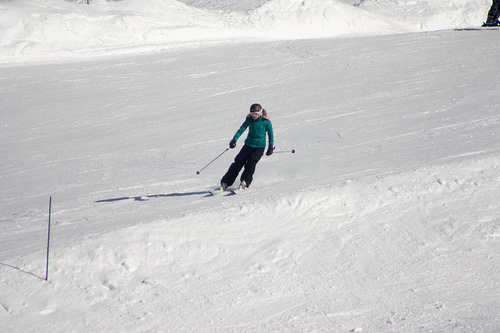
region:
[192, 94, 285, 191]
woman skiing down the mountain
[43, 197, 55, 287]
purple sticking out the snow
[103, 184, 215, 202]
woman's shadow on the snow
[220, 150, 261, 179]
black pants of woman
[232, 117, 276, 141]
green jacket of woman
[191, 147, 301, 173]
ski poles in woman's hands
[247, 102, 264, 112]
knit cap of the woman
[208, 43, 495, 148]
tracks in the snow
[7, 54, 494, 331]
mountain woman is skiing on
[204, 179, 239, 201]
white skis of woman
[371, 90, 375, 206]
part of a hill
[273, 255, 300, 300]
edge of a hill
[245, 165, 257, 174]
part of a trouser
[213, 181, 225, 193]
part of a board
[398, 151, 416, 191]
edge of a hill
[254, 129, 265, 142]
part of a sweater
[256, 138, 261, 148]
part of a jacket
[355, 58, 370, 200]
part of a slope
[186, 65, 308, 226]
lady in green skiing down a hill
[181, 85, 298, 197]
lady skier skiing down a hill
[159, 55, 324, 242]
lady in green with ski poles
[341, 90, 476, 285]
ski tracks on a ski slope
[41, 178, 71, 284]
ski pole on a ski slope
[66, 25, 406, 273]
lady skiing in green jacket down a slope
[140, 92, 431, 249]
lady skiing in green jacket down a slope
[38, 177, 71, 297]
small pole in the snow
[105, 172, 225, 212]
person shadow in the snow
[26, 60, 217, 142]
smooth snow on the hill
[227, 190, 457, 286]
bright shinny snow on the hill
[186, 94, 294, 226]
skier on a small hill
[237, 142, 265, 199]
skier with black paints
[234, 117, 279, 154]
skier with green top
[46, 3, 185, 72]
piles of snow in the background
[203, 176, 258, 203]
skier with snow covered skis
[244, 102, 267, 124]
skier with white gaggles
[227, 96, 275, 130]
woman has dark helmet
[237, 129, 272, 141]
woman has green coat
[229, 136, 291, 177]
woman has black gloves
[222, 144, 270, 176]
woman has black pants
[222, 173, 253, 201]
woman has white boots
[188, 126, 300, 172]
woman holds ski poles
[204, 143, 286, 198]
woman has white skis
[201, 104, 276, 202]
woman is turning into corner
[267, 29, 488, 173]
snow is packed on track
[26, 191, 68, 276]
black pole near track